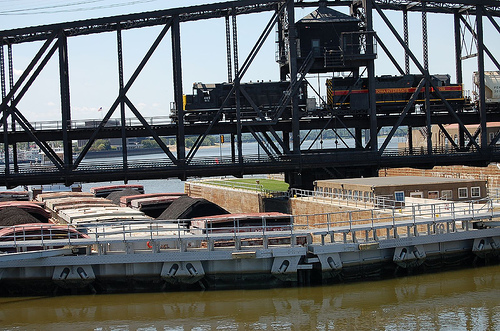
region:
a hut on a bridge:
[282, 1, 367, 71]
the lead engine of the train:
[169, 79, 308, 122]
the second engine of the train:
[314, 73, 476, 114]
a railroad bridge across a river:
[0, 0, 497, 185]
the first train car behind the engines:
[468, 71, 498, 112]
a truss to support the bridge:
[72, 16, 172, 168]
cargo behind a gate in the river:
[0, 187, 323, 247]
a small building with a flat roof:
[314, 175, 489, 205]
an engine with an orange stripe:
[320, 77, 470, 109]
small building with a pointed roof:
[287, 1, 362, 68]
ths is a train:
[326, 68, 461, 121]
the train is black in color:
[328, 65, 450, 115]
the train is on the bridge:
[326, 67, 452, 118]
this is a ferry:
[159, 158, 471, 275]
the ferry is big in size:
[207, 159, 419, 253]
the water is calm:
[343, 278, 397, 322]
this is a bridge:
[75, 7, 189, 87]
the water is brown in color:
[338, 290, 400, 330]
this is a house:
[300, 11, 353, 50]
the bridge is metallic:
[271, 111, 360, 158]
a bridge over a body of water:
[1, 0, 499, 213]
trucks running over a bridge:
[1, 66, 499, 146]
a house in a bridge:
[248, 2, 414, 143]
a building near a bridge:
[313, 163, 495, 235]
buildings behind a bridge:
[0, 111, 274, 165]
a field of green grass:
[200, 171, 307, 198]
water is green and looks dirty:
[22, 272, 497, 329]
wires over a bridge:
[5, 3, 185, 88]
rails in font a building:
[286, 176, 398, 218]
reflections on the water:
[0, 270, 499, 329]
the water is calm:
[180, 275, 475, 323]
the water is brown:
[208, 272, 465, 324]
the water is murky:
[187, 272, 456, 325]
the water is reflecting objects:
[120, 276, 455, 326]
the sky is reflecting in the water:
[301, 291, 488, 327]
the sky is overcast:
[2, 5, 409, 137]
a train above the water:
[88, 55, 483, 137]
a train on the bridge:
[0, 15, 495, 161]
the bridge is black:
[0, 5, 480, 165]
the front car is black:
[106, 46, 334, 133]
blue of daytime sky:
[1, 3, 497, 123]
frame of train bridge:
[1, 5, 496, 180]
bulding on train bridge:
[286, 2, 378, 68]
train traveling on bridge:
[173, 71, 497, 132]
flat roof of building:
[317, 174, 486, 199]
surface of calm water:
[0, 268, 499, 329]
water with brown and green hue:
[1, 262, 496, 327]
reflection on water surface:
[0, 268, 499, 328]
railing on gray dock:
[0, 199, 494, 254]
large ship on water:
[81, 143, 169, 160]